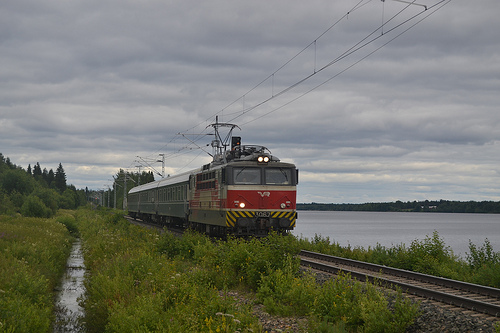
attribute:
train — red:
[121, 115, 298, 236]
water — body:
[288, 209, 498, 264]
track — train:
[290, 246, 499, 313]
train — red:
[174, 153, 306, 223]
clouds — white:
[345, 81, 491, 192]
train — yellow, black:
[222, 142, 305, 244]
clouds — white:
[115, 13, 296, 111]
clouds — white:
[32, 56, 127, 121]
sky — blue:
[16, 20, 221, 98]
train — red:
[117, 145, 298, 234]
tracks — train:
[123, 213, 498, 313]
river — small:
[284, 210, 480, 259]